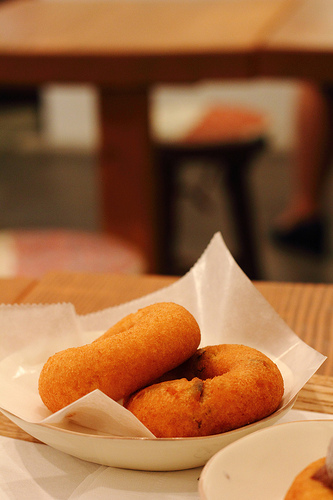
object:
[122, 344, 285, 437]
donuts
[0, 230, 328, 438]
paper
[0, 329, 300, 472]
plate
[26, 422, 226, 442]
edge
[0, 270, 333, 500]
table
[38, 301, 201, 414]
donut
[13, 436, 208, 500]
shadow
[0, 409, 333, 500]
paper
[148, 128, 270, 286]
stool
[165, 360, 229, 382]
hole